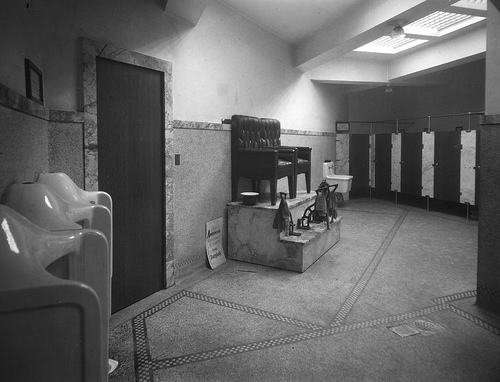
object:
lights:
[447, 0, 488, 12]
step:
[282, 210, 342, 273]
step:
[227, 188, 323, 238]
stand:
[227, 190, 342, 273]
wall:
[0, 0, 339, 291]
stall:
[348, 134, 369, 190]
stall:
[401, 132, 424, 195]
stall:
[375, 133, 392, 192]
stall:
[433, 130, 461, 204]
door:
[433, 129, 461, 204]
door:
[401, 130, 422, 198]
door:
[375, 132, 391, 192]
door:
[349, 136, 370, 187]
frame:
[25, 58, 45, 106]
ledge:
[0, 81, 84, 126]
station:
[163, 109, 482, 273]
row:
[335, 128, 483, 212]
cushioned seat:
[230, 114, 296, 205]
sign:
[24, 59, 45, 107]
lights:
[351, 34, 429, 56]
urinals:
[39, 170, 113, 240]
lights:
[399, 10, 486, 38]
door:
[94, 53, 167, 318]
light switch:
[175, 154, 180, 165]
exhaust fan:
[353, 32, 428, 54]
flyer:
[205, 216, 228, 270]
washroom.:
[0, 0, 500, 382]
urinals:
[0, 205, 113, 382]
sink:
[322, 160, 354, 203]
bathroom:
[0, 0, 500, 381]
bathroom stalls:
[432, 130, 462, 204]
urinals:
[2, 182, 113, 277]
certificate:
[23, 58, 45, 107]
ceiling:
[215, 0, 483, 94]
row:
[0, 172, 118, 382]